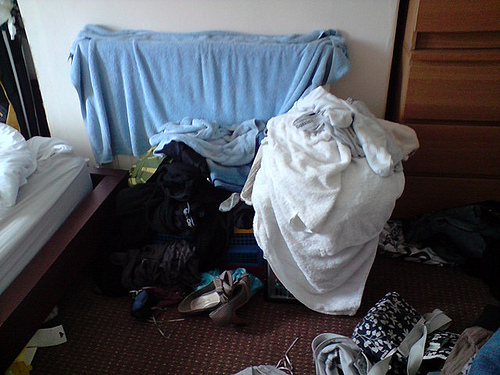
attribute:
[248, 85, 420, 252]
towels — white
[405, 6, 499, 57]
drawer — wooden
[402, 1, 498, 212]
cabinet — wood